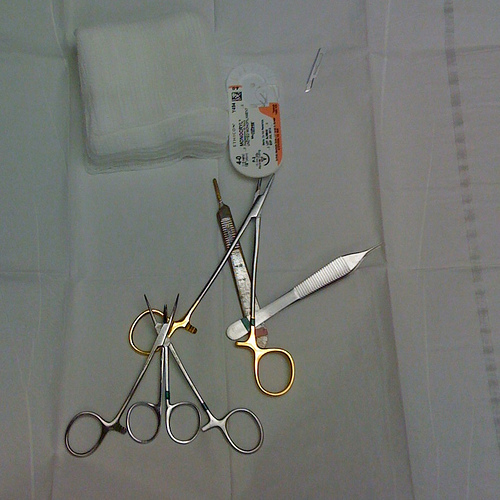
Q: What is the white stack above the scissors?
A: Gauze.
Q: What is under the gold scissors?
A: Tweezers.